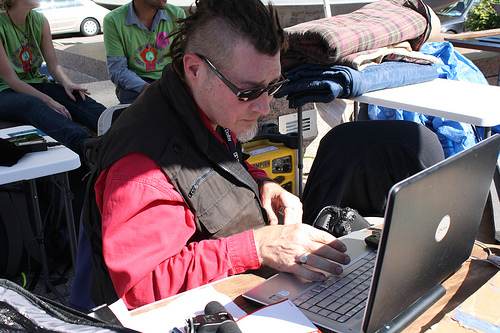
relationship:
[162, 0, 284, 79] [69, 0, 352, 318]
mohawk on man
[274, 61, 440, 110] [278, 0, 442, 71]
blanket below or blanket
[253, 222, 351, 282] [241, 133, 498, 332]
right-hand touching laptop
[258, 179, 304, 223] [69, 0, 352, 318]
left-hand of man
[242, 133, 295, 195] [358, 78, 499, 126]
box laying under table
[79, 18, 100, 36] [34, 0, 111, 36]
back tire of car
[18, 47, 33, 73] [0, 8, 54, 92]
ribbon on tank-top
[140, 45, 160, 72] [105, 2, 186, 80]
ribbon on shirt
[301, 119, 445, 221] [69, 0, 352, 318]
jacket draped nex to man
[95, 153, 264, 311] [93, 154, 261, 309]
sleeve of shirt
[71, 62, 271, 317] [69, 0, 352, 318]
vest worn by man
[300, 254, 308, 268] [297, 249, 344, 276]
ring on finger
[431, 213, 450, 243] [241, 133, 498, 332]
emblem on laptop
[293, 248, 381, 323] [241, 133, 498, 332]
keyboard of laptop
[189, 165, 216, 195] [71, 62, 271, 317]
zipper on vest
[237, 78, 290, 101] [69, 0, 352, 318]
sunglasses on man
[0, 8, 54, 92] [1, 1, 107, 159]
tank-top on woman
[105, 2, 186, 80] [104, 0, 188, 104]
shirt on man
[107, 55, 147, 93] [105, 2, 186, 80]
sleeve under shirt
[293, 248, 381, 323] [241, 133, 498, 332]
keyboard on laptop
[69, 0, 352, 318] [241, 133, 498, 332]
man using laptop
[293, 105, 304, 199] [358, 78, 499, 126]
leg of table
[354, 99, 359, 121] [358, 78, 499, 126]
leg of table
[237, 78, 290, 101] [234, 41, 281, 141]
sunglasses on face